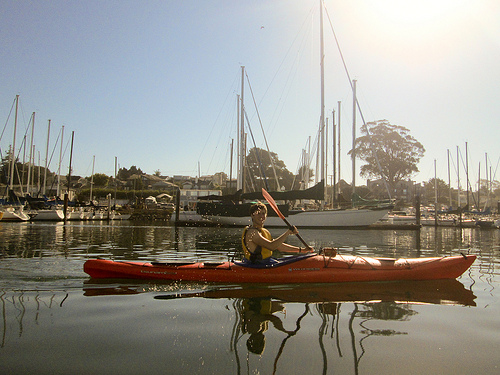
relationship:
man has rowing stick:
[236, 201, 317, 263] [264, 182, 314, 254]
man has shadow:
[236, 201, 317, 263] [162, 277, 293, 310]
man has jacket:
[236, 201, 317, 263] [240, 225, 276, 262]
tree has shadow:
[356, 112, 431, 229] [352, 287, 425, 338]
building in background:
[167, 172, 225, 207] [1, 6, 479, 230]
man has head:
[236, 201, 317, 263] [252, 201, 267, 225]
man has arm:
[236, 201, 317, 263] [249, 221, 295, 252]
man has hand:
[236, 201, 317, 263] [284, 226, 305, 239]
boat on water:
[84, 250, 480, 284] [7, 210, 499, 374]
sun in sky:
[306, 5, 500, 71] [1, 2, 500, 196]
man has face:
[236, 201, 317, 263] [254, 207, 266, 225]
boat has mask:
[184, 177, 398, 231] [186, 194, 297, 219]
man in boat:
[236, 201, 317, 263] [84, 250, 480, 284]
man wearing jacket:
[236, 201, 317, 263] [240, 225, 276, 262]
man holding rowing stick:
[236, 201, 317, 263] [264, 182, 314, 254]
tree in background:
[356, 112, 431, 229] [1, 6, 479, 230]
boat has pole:
[184, 177, 398, 231] [313, 5, 338, 214]